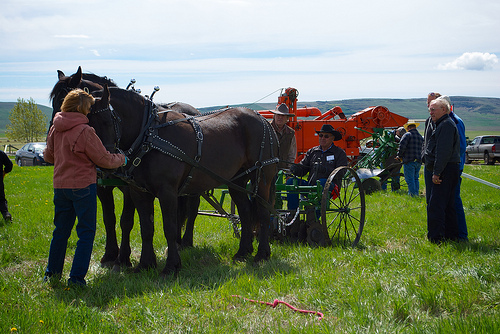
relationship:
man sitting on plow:
[278, 117, 351, 236] [279, 175, 335, 248]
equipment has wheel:
[256, 86, 408, 172] [313, 160, 374, 247]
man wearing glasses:
[278, 117, 351, 236] [311, 129, 334, 143]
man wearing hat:
[278, 117, 351, 236] [306, 115, 353, 147]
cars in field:
[14, 140, 54, 170] [12, 155, 48, 187]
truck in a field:
[460, 126, 496, 176] [473, 167, 499, 189]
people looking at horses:
[402, 83, 479, 243] [98, 72, 300, 278]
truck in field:
[460, 126, 496, 176] [12, 155, 48, 187]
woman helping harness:
[29, 81, 132, 291] [91, 139, 137, 183]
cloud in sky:
[0, 0, 499, 107] [123, 14, 230, 54]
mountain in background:
[1, 89, 60, 126] [12, 52, 488, 126]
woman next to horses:
[29, 81, 132, 291] [98, 72, 300, 278]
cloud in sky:
[179, 19, 232, 66] [123, 14, 230, 54]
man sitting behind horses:
[278, 117, 351, 236] [98, 72, 300, 278]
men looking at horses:
[402, 83, 479, 243] [98, 72, 300, 278]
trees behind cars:
[7, 103, 48, 143] [14, 135, 54, 170]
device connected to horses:
[313, 160, 374, 247] [98, 72, 300, 278]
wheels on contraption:
[313, 160, 374, 247] [264, 154, 369, 247]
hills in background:
[329, 74, 430, 137] [12, 52, 488, 126]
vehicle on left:
[14, 135, 54, 170] [8, 142, 52, 163]